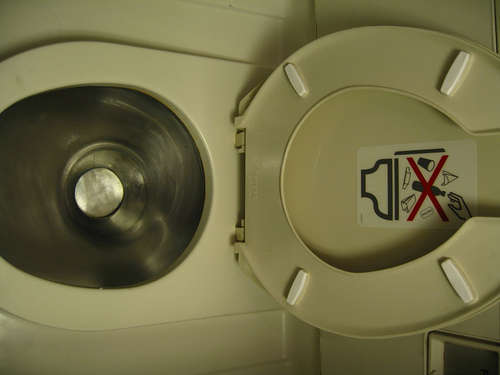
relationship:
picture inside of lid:
[352, 138, 474, 231] [237, 16, 499, 344]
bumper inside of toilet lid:
[281, 60, 308, 100] [228, 20, 499, 341]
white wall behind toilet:
[208, 329, 309, 373] [5, 26, 241, 356]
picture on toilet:
[352, 138, 474, 231] [2, 24, 264, 349]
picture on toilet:
[352, 138, 474, 231] [2, 18, 494, 335]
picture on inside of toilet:
[352, 138, 474, 231] [88, 33, 498, 311]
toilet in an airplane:
[0, 26, 500, 350] [0, 18, 480, 361]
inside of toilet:
[15, 118, 151, 249] [2, 18, 494, 335]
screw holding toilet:
[232, 222, 252, 244] [2, 18, 494, 335]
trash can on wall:
[423, 328, 498, 372] [312, 2, 497, 373]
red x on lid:
[405, 152, 451, 225] [237, 16, 499, 344]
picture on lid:
[352, 138, 474, 231] [237, 16, 499, 344]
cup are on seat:
[416, 154, 440, 174] [27, 22, 229, 344]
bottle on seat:
[76, 117, 208, 310] [27, 22, 229, 344]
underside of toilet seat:
[240, 27, 498, 342] [231, 19, 499, 341]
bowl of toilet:
[0, 49, 252, 333] [2, 32, 499, 359]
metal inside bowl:
[129, 126, 190, 266] [0, 49, 252, 333]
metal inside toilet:
[129, 126, 190, 266] [2, 32, 499, 359]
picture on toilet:
[352, 138, 474, 236] [2, 18, 494, 335]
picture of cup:
[352, 138, 474, 236] [416, 154, 440, 174]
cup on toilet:
[416, 154, 440, 174] [2, 18, 494, 335]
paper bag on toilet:
[398, 192, 419, 212] [2, 18, 494, 335]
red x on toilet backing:
[408, 152, 446, 224] [233, 19, 498, 337]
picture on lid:
[352, 138, 474, 231] [267, 42, 461, 302]